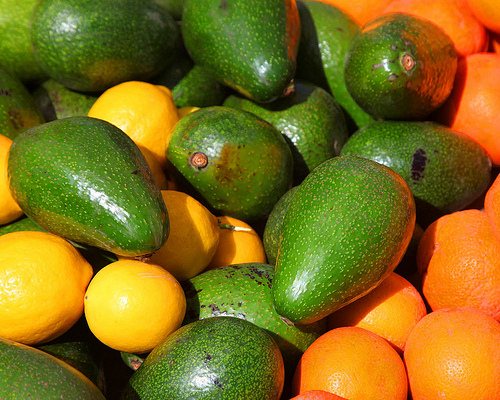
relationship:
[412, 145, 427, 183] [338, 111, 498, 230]
blemish covering fruit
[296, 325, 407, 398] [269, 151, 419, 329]
orange lying underneath fruit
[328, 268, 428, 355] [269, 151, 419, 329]
orange lying underneath fruit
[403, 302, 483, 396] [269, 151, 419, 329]
orange lying underneath fruit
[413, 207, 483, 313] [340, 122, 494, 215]
orange lying underneath avocado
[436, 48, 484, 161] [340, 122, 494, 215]
orange lying underneath avocado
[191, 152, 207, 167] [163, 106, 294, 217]
stem belonging to avocado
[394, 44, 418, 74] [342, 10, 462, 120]
stem belonging to fruit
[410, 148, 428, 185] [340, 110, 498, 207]
blemish covering avocado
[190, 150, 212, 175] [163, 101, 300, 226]
stem belonging to avocado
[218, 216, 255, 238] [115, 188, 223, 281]
stem belonging to lemon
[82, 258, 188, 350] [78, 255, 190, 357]
rind covering lemon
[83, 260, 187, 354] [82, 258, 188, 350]
rind covering rind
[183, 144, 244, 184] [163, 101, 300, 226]
bruise covering avocado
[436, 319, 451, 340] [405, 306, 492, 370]
spotting covering orange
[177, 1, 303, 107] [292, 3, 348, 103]
avocado casting shadow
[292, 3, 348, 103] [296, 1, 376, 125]
shadow casted on avocado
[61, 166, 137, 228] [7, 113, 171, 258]
light shining on fruit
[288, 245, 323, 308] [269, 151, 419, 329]
light shining on fruit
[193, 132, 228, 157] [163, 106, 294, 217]
light shining on avocado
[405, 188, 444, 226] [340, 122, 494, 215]
shadow casted on avocado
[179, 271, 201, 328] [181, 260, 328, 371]
shadow casted on fruit